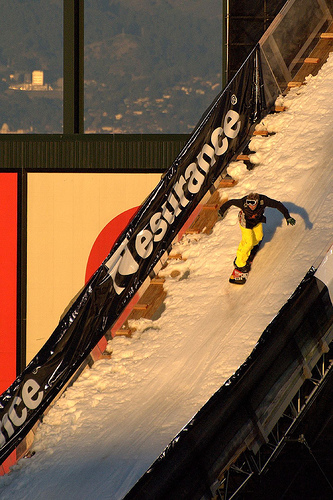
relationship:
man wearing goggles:
[218, 192, 297, 274] [246, 199, 256, 205]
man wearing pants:
[218, 192, 297, 274] [233, 222, 262, 266]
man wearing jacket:
[218, 192, 297, 274] [216, 196, 286, 224]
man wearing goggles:
[218, 192, 297, 274] [241, 197, 254, 203]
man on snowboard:
[218, 192, 297, 274] [229, 244, 253, 287]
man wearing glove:
[218, 192, 297, 274] [287, 215, 295, 224]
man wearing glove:
[215, 193, 302, 271] [217, 210, 224, 216]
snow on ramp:
[185, 316, 212, 352] [0, 25, 333, 498]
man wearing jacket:
[218, 192, 297, 274] [218, 192, 291, 231]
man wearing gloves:
[218, 192, 297, 274] [285, 216, 298, 228]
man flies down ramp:
[218, 192, 297, 274] [180, 115, 293, 358]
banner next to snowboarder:
[105, 139, 213, 290] [218, 181, 274, 290]